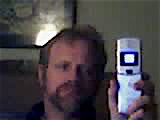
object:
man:
[23, 24, 108, 120]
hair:
[38, 24, 108, 80]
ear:
[34, 64, 45, 89]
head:
[37, 23, 108, 112]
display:
[120, 51, 138, 66]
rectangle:
[120, 51, 139, 66]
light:
[124, 54, 135, 64]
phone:
[114, 37, 144, 115]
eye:
[55, 62, 71, 72]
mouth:
[58, 85, 84, 98]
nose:
[67, 66, 80, 82]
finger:
[134, 80, 145, 91]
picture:
[0, 0, 78, 50]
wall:
[93, 3, 130, 34]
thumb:
[107, 80, 117, 113]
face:
[48, 45, 100, 112]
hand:
[108, 72, 156, 120]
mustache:
[56, 82, 85, 96]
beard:
[48, 81, 95, 113]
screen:
[117, 38, 141, 73]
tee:
[24, 99, 45, 120]